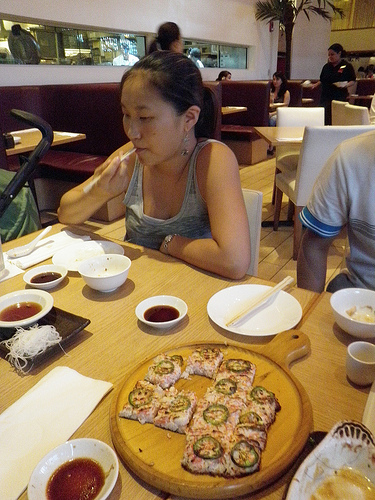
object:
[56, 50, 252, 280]
woman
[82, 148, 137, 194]
chopsticks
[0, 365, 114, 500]
napkin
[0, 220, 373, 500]
table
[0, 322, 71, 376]
noodles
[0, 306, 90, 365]
plate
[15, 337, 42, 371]
corner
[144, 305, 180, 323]
sauce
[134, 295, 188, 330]
bowl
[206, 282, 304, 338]
plate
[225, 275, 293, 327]
chopstick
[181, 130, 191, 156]
earrings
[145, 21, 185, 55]
person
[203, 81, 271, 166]
booth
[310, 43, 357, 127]
person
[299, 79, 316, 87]
food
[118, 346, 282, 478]
pizza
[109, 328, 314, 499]
board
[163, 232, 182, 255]
watch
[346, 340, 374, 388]
cup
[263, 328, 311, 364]
handle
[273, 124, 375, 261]
chair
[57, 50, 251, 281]
diner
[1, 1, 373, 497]
restaurant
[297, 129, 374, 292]
diner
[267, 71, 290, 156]
diner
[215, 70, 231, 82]
diner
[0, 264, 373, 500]
food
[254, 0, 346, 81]
tree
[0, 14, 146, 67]
window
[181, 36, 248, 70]
window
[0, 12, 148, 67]
kitchen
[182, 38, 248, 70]
kitchen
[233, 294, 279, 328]
shadow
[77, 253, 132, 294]
bowl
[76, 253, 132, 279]
edge